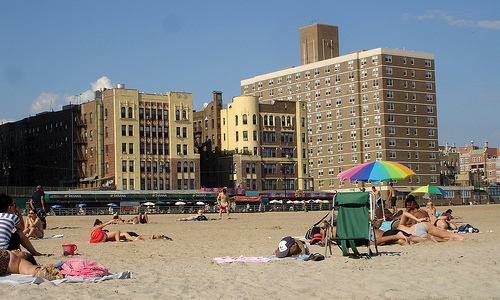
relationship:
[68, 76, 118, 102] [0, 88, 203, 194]
steam above building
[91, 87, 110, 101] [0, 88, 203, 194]
chimney on building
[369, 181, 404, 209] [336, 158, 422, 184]
people under umbrella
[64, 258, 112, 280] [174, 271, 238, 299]
blanket on sand